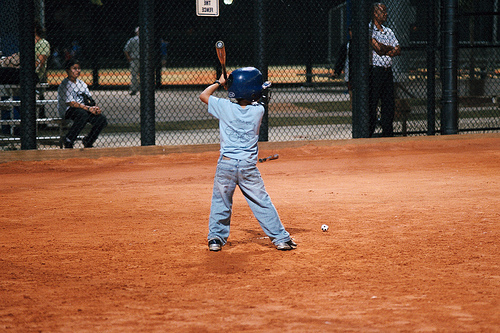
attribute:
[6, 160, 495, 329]
ground — clay, brown, red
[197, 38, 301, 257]
boy — young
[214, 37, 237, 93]
bat — brown, black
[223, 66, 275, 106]
helmet — blue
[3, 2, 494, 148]
fence — metal, chain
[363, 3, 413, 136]
man — watching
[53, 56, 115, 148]
kid — sitting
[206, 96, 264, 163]
shirt — gray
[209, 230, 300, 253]
shoes — gray